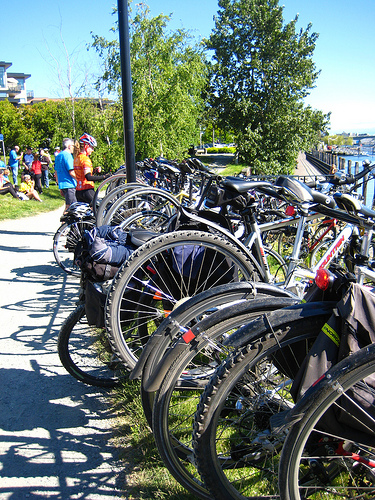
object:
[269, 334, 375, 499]
bikes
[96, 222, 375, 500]
grass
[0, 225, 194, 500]
shadow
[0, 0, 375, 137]
sky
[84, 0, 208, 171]
trees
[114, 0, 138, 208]
pole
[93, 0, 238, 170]
middle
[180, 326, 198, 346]
reflector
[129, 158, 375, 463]
bike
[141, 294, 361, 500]
tire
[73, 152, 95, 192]
shirt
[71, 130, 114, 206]
person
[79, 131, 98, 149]
helmet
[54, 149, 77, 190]
shirt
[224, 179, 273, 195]
seat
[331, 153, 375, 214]
water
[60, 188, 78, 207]
shorts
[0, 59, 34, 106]
building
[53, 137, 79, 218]
man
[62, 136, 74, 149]
gray hair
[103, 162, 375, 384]
bicycle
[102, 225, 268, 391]
rear tire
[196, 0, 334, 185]
tree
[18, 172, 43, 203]
woman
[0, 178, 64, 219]
grass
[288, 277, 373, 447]
bikebag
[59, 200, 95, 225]
helmet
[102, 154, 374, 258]
bike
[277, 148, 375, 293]
front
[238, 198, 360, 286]
frame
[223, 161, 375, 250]
rack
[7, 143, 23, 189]
people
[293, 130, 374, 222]
beach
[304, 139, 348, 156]
dock